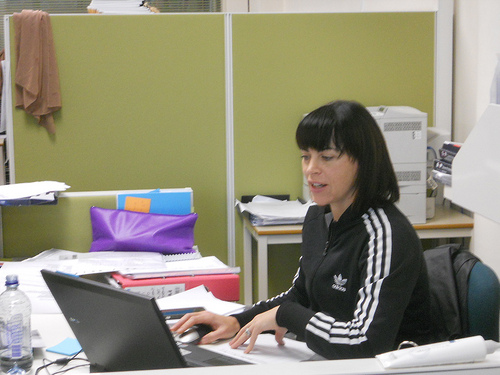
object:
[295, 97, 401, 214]
hair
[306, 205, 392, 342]
stripes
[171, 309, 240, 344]
hand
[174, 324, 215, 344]
mouse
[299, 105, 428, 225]
printer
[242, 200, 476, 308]
table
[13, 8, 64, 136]
sweater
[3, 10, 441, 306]
wall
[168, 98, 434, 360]
woman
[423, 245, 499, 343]
chair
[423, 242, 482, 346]
coat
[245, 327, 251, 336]
ring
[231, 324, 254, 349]
finger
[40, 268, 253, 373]
laptop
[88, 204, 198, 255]
bag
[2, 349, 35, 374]
water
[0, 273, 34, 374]
bottle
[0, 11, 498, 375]
cubicle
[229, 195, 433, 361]
jacket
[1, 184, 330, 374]
desk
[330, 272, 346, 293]
logo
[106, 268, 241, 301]
binder